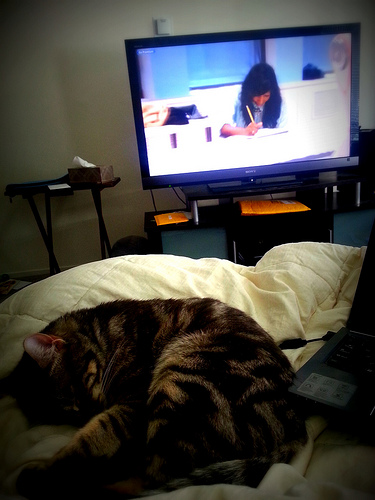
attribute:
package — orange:
[153, 209, 187, 226]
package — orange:
[236, 197, 310, 218]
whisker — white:
[97, 352, 124, 395]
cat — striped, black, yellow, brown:
[2, 293, 310, 497]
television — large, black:
[122, 20, 360, 193]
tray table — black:
[15, 181, 124, 265]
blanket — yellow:
[6, 234, 374, 371]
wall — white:
[3, 4, 372, 293]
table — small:
[11, 162, 124, 272]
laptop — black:
[262, 243, 373, 416]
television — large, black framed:
[124, 13, 359, 176]